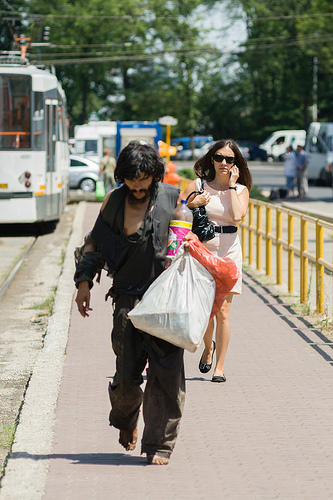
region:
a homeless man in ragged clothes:
[66, 135, 199, 472]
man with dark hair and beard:
[106, 140, 173, 220]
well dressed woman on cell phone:
[182, 136, 254, 386]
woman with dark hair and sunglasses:
[189, 134, 249, 188]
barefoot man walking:
[98, 399, 196, 478]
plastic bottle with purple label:
[163, 196, 194, 272]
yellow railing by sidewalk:
[258, 197, 332, 318]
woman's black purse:
[186, 188, 219, 243]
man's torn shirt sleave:
[69, 229, 115, 291]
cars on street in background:
[167, 125, 332, 169]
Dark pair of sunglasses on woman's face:
[212, 152, 235, 164]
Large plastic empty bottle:
[166, 199, 193, 267]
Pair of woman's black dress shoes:
[200, 343, 224, 381]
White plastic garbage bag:
[128, 255, 216, 353]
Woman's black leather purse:
[187, 180, 215, 238]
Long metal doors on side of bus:
[45, 99, 55, 218]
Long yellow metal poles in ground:
[241, 198, 331, 328]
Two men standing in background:
[282, 142, 311, 195]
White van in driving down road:
[259, 129, 305, 157]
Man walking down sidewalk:
[98, 149, 116, 191]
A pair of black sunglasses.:
[211, 153, 237, 163]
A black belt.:
[213, 226, 242, 232]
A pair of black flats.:
[196, 334, 227, 382]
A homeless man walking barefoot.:
[72, 135, 240, 475]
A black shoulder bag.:
[184, 177, 216, 240]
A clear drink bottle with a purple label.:
[167, 197, 193, 260]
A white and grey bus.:
[0, 53, 70, 237]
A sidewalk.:
[43, 177, 330, 499]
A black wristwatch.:
[228, 185, 237, 191]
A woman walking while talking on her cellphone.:
[182, 138, 260, 384]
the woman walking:
[181, 141, 250, 381]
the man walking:
[66, 138, 191, 463]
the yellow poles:
[239, 190, 330, 313]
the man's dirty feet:
[113, 422, 166, 465]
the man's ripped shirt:
[67, 182, 179, 298]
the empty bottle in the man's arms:
[163, 196, 194, 269]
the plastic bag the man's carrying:
[127, 240, 240, 351]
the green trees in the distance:
[2, 2, 330, 139]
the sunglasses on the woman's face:
[210, 153, 234, 162]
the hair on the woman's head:
[193, 140, 252, 190]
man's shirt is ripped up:
[75, 187, 150, 265]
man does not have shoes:
[95, 425, 184, 474]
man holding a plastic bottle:
[162, 197, 200, 272]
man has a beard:
[125, 173, 152, 203]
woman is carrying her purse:
[189, 194, 222, 234]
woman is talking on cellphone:
[218, 157, 242, 174]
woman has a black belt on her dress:
[199, 218, 247, 235]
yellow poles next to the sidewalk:
[275, 191, 325, 268]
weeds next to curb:
[45, 275, 58, 313]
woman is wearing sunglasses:
[208, 150, 243, 165]